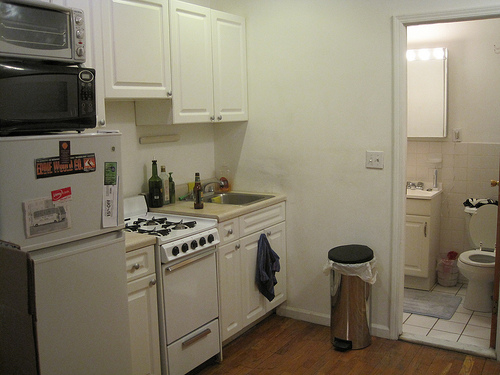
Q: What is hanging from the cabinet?
A: Towel.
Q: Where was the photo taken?
A: In a kitchen.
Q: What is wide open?
A: Bathroom door.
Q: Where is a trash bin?
A: On the floor.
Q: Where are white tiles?
A: On bathroom floor.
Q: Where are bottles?
A: On the countertop.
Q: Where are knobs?
A: On cabinets and drawers.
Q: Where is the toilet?
A: In the bathroom.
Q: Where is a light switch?
A: On the wall.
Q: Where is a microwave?
A: On top of the fridge.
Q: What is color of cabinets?
A: White.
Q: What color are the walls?
A: White.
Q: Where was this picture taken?
A: A kitchen.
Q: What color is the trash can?
A: Silver.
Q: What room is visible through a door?
A: Bathroom.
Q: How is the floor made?
A: Of wood.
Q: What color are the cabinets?
A: Off white.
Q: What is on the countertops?
A: Bottles.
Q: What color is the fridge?
A: White.